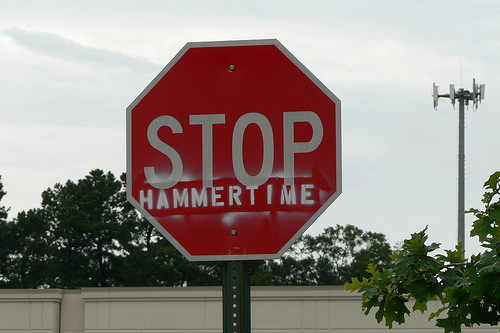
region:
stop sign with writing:
[108, 33, 362, 255]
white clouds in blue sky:
[341, 166, 388, 193]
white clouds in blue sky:
[375, 155, 412, 202]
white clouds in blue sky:
[344, 42, 385, 102]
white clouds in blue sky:
[334, 21, 376, 65]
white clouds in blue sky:
[58, 119, 92, 140]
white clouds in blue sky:
[47, 126, 98, 163]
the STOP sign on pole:
[116, 25, 356, 270]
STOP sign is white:
[139, 102, 324, 207]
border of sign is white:
[114, 28, 356, 275]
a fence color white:
[1, 273, 493, 330]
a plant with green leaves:
[341, 170, 496, 330]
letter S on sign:
[139, 102, 193, 197]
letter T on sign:
[184, 104, 228, 192]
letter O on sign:
[231, 110, 276, 190]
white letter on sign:
[141, 110, 190, 188]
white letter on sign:
[187, 110, 227, 185]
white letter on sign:
[230, 110, 274, 184]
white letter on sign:
[281, 106, 325, 185]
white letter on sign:
[136, 186, 158, 212]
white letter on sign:
[155, 186, 171, 214]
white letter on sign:
[171, 184, 191, 211]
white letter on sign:
[186, 185, 212, 210]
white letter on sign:
[208, 184, 226, 209]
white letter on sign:
[223, 181, 243, 208]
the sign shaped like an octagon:
[125, 38, 342, 262]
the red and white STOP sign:
[125, 38, 342, 260]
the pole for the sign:
[221, 260, 250, 331]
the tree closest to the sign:
[342, 170, 497, 332]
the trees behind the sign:
[1, 167, 395, 288]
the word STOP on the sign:
[143, 112, 323, 187]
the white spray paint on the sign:
[137, 168, 329, 223]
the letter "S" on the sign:
[143, 114, 183, 189]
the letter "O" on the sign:
[232, 111, 273, 186]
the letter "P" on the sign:
[282, 110, 323, 185]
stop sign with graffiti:
[100, 35, 360, 265]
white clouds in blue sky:
[352, 203, 393, 221]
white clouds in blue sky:
[358, 82, 402, 146]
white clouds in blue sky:
[308, 22, 379, 57]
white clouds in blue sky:
[15, 26, 77, 81]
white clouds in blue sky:
[34, 71, 79, 159]